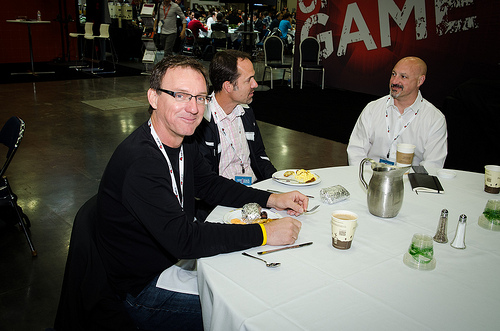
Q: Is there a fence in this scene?
A: No, there are no fences.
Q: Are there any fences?
A: No, there are no fences.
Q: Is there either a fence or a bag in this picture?
A: No, there are no fences or bags.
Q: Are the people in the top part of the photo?
A: Yes, the people are in the top of the image.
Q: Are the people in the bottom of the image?
A: No, the people are in the top of the image.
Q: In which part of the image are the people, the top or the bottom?
A: The people are in the top of the image.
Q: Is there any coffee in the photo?
A: Yes, there is coffee.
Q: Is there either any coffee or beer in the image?
A: Yes, there is coffee.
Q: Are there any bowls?
A: No, there are no bowls.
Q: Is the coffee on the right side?
A: Yes, the coffee is on the right of the image.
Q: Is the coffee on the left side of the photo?
A: No, the coffee is on the right of the image.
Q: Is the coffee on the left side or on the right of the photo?
A: The coffee is on the right of the image.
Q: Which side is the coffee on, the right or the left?
A: The coffee is on the right of the image.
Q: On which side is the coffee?
A: The coffee is on the right of the image.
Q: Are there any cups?
A: Yes, there is a cup.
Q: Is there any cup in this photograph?
A: Yes, there is a cup.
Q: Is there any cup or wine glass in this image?
A: Yes, there is a cup.